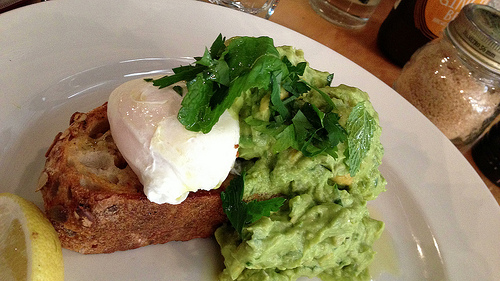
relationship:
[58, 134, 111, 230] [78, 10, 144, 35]
bread on plate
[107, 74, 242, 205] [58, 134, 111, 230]
butter on bread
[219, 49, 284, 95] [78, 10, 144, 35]
leaves on plate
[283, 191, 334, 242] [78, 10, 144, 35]
guacamole on plate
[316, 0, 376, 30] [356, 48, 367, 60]
glass on table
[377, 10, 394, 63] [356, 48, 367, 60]
bottle on table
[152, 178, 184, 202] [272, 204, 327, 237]
butter on meat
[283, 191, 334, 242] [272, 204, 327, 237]
guacamole near meat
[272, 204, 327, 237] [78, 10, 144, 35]
meat on plate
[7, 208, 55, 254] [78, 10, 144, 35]
lemon on plate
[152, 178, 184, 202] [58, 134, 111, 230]
butter on bread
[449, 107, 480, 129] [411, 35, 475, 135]
spices in jar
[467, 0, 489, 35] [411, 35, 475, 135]
lid on jar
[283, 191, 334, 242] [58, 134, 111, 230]
guacamole on bread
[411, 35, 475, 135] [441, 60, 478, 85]
jar of cheese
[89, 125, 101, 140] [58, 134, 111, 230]
oats on bread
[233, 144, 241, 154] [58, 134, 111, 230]
crumb on bread